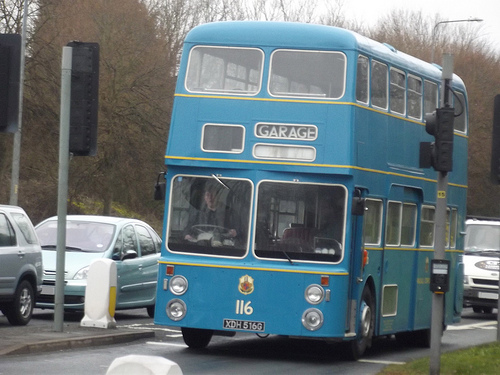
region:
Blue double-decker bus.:
[139, 19, 469, 362]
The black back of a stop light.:
[66, 40, 103, 157]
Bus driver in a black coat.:
[182, 185, 242, 248]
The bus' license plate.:
[221, 318, 266, 333]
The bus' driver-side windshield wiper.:
[210, 172, 232, 191]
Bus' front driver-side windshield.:
[165, 173, 256, 258]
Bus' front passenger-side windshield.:
[250, 178, 348, 264]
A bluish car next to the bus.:
[33, 213, 163, 305]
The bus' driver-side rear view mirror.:
[154, 170, 169, 205]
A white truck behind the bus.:
[462, 214, 498, 314]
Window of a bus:
[161, 165, 257, 282]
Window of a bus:
[254, 180, 349, 274]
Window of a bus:
[184, 45, 266, 100]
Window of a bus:
[264, 45, 351, 107]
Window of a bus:
[198, 113, 248, 163]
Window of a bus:
[352, 191, 385, 250]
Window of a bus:
[379, 195, 404, 250]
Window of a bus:
[403, 200, 420, 249]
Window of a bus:
[377, 285, 399, 320]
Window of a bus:
[360, 56, 372, 113]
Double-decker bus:
[151, 23, 470, 361]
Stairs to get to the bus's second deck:
[311, 152, 431, 257]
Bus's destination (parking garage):
[253, 119, 320, 141]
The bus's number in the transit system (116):
[234, 296, 253, 316]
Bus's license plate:
[220, 318, 265, 334]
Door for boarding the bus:
[374, 177, 421, 346]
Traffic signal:
[51, 37, 96, 337]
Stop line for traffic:
[143, 336, 414, 373]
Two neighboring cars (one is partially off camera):
[0, 198, 177, 335]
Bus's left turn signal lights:
[319, 245, 373, 290]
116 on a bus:
[233, 297, 253, 314]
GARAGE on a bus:
[252, 120, 317, 138]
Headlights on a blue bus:
[167, 275, 327, 330]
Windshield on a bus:
[155, 171, 347, 261]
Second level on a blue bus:
[158, 11, 478, 193]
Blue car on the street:
[23, 212, 164, 317]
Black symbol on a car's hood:
[471, 255, 499, 275]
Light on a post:
[426, 10, 488, 52]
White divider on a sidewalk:
[76, 257, 119, 329]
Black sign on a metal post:
[56, 39, 98, 334]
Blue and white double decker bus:
[151, 20, 468, 360]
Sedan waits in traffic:
[34, 213, 159, 320]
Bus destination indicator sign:
[252, 119, 317, 142]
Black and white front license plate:
[221, 317, 264, 332]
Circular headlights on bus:
[165, 274, 324, 331]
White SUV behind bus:
[460, 216, 499, 319]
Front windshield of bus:
[165, 173, 347, 263]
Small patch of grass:
[378, 340, 498, 371]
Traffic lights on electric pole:
[51, 39, 100, 334]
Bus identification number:
[232, 299, 253, 315]